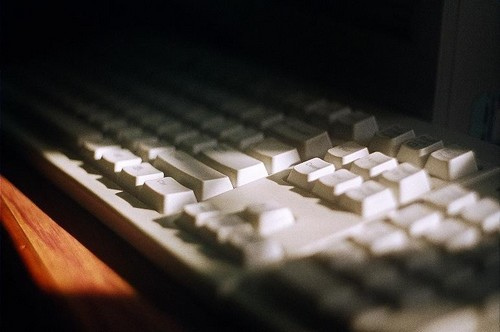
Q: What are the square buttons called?
A: Keys.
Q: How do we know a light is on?
A: Shadow on the keyboard.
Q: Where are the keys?
A: Keyboard.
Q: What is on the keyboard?
A: Light.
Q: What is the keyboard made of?
A: Plastic.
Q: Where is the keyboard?
A: On the table.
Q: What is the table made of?
A: Wood.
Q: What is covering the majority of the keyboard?
A: A shadow.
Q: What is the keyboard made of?
A: Plastic.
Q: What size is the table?
A: Small.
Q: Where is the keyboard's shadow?
A: On the table.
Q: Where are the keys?
A: On the keyboard.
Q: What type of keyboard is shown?
A: Computer.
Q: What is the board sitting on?
A: A desk.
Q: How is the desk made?
A: Of wood.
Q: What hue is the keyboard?
A: White.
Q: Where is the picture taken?
A: A home office.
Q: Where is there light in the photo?
A: Lower right side.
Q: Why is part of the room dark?
A: Because only natural light was available.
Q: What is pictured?
A: A keyboard.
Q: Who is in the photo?
A: Nobody.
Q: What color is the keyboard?
A: White.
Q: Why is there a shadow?
A: Light is shining in.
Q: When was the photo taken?
A: Daytime.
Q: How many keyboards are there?
A: One.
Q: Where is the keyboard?
A: On the desk.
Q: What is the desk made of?
A: Wood.